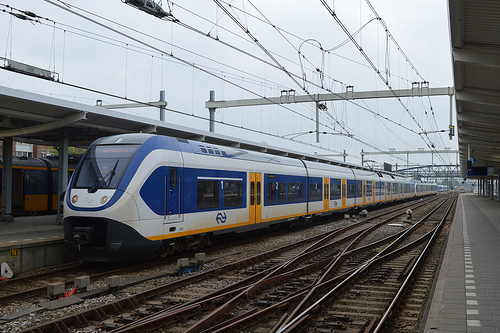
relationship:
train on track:
[58, 127, 446, 263] [15, 190, 473, 326]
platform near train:
[6, 192, 106, 271] [58, 127, 446, 263]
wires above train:
[1, 3, 466, 171] [58, 127, 446, 263]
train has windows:
[58, 127, 446, 263] [85, 150, 393, 197]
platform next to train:
[6, 192, 106, 271] [58, 127, 446, 263]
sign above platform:
[460, 149, 497, 177] [415, 181, 499, 332]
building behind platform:
[6, 133, 68, 160] [6, 192, 106, 271]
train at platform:
[58, 127, 446, 263] [6, 192, 106, 271]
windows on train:
[85, 150, 393, 197] [58, 127, 446, 263]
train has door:
[58, 127, 446, 263] [165, 163, 273, 222]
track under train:
[15, 190, 473, 326] [58, 127, 446, 263]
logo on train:
[208, 209, 230, 227] [58, 127, 446, 263]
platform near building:
[6, 192, 106, 271] [6, 133, 68, 160]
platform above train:
[6, 192, 106, 271] [58, 127, 446, 263]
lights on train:
[65, 189, 112, 208] [58, 127, 446, 263]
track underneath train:
[15, 190, 473, 326] [58, 127, 446, 263]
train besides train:
[5, 149, 77, 213] [58, 127, 446, 263]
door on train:
[165, 163, 273, 222] [58, 127, 446, 263]